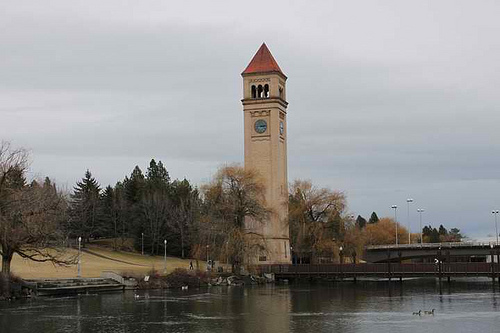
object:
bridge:
[361, 242, 500, 263]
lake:
[0, 275, 497, 331]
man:
[189, 261, 193, 270]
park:
[0, 136, 500, 333]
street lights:
[391, 205, 398, 209]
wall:
[245, 136, 274, 264]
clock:
[254, 119, 267, 133]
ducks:
[424, 308, 435, 314]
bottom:
[396, 230, 398, 244]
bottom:
[408, 227, 410, 244]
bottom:
[420, 232, 422, 244]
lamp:
[407, 199, 414, 203]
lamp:
[417, 209, 424, 212]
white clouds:
[421, 178, 500, 207]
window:
[264, 84, 270, 98]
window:
[258, 84, 263, 98]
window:
[251, 84, 257, 98]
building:
[239, 41, 292, 263]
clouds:
[0, 84, 92, 142]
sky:
[0, 0, 500, 239]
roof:
[241, 42, 288, 79]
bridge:
[247, 262, 500, 278]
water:
[0, 276, 500, 332]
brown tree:
[0, 142, 81, 302]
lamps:
[488, 210, 499, 215]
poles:
[394, 208, 399, 245]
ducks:
[413, 309, 421, 313]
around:
[0, 139, 500, 333]